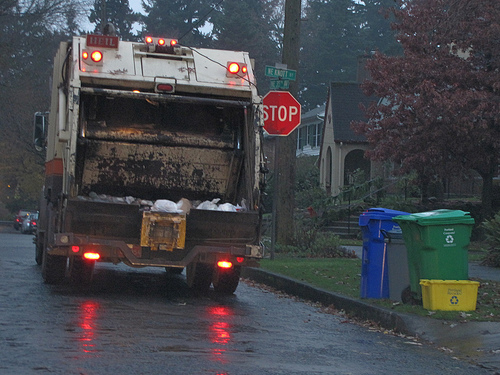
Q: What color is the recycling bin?
A: Green.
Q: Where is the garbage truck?
A: In front of the stop sign.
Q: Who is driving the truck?
A: The garbage man.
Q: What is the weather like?
A: Rainy.